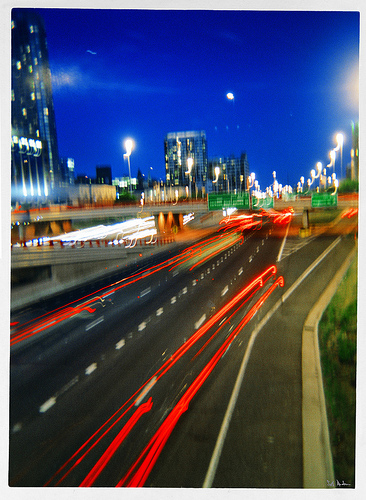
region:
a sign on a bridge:
[207, 191, 252, 209]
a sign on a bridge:
[310, 192, 338, 207]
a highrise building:
[162, 130, 206, 194]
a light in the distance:
[124, 139, 132, 153]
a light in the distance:
[335, 132, 342, 146]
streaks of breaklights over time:
[53, 264, 285, 497]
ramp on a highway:
[11, 239, 179, 304]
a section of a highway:
[14, 210, 362, 499]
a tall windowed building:
[10, 12, 67, 199]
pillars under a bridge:
[154, 214, 186, 232]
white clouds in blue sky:
[63, 29, 99, 67]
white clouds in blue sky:
[120, 44, 175, 88]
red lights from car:
[209, 276, 273, 336]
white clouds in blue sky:
[131, 64, 164, 103]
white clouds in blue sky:
[250, 35, 292, 57]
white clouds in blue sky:
[300, 78, 336, 124]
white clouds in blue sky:
[81, 105, 109, 128]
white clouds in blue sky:
[114, 27, 145, 69]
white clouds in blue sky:
[148, 81, 173, 115]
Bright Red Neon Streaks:
[49, 258, 298, 490]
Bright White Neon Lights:
[25, 209, 206, 250]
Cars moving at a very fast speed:
[9, 192, 348, 487]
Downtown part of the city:
[12, 7, 365, 205]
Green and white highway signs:
[204, 189, 342, 213]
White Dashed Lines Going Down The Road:
[27, 223, 281, 457]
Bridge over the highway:
[12, 189, 357, 235]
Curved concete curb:
[291, 229, 364, 493]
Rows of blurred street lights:
[103, 119, 353, 194]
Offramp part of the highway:
[267, 167, 355, 320]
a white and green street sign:
[206, 189, 231, 210]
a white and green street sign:
[228, 189, 250, 209]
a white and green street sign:
[250, 195, 271, 207]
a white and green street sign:
[309, 192, 337, 207]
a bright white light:
[124, 136, 139, 179]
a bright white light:
[333, 131, 343, 174]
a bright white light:
[315, 159, 322, 181]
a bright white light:
[225, 87, 235, 104]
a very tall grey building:
[163, 128, 207, 187]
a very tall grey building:
[210, 150, 247, 192]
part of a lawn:
[314, 390, 344, 417]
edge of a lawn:
[334, 362, 346, 380]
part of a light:
[153, 450, 165, 464]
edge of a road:
[261, 418, 271, 441]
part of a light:
[169, 418, 175, 427]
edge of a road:
[292, 408, 295, 412]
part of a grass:
[340, 360, 348, 367]